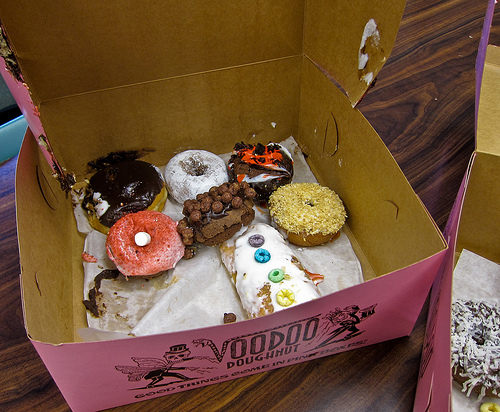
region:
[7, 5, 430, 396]
a box of donuts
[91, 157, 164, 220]
a chocolate glazed donut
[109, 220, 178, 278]
a pink donut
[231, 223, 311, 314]
a white donut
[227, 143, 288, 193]
a donut with orange frosting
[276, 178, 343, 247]
a donut with tan sprinkles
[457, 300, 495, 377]
a donut with coconut on it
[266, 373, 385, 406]
the wood table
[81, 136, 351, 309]
seven donuts in a box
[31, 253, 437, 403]
the side of the pink box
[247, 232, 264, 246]
purple Froot Loop on donut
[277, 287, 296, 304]
yellow Froot Loop on the donut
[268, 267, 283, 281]
green Froot Loop on the donut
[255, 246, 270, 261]
blue Froot Loop on a donut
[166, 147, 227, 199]
round powdered sugar donut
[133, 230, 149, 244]
small white marshmallow on pink donut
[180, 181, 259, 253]
donut with Cocoa Puffs on it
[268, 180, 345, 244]
round donut with coconut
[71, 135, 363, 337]
white paper under the donuts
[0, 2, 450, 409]
pink Voodoo Donut cardboard box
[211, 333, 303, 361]
a pink box written on voodoo doughnut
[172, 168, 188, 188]
ice on a doughnut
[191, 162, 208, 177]
a hole on a doughnut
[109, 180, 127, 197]
jam on a doughnut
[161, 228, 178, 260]
pink ice on a doughnut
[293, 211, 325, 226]
yellow ice on a doughnut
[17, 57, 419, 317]
a box full of doughnuts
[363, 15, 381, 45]
remains of a ice on the doughnut box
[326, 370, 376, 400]
a wooden table with doughnut boxes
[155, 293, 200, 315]
a white napkin in the doughnut box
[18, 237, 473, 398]
doughnut box is pink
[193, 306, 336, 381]
Voodoo doughnut is the name of the company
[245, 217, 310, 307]
long white donut with color circles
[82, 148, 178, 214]
chocolate frosting donut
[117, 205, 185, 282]
doughnut is red with marshmellow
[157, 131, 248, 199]
white powedered doughnut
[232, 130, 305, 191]
chocolate doughnut with red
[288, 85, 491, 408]
two boxes of donuts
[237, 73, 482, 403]
boxes on the table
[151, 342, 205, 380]
skull people on the box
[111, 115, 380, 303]
snacks are in a box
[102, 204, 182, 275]
the doughnut is red in colour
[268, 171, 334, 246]
the cake is yellow in colour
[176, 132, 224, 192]
the doughnut is white in colour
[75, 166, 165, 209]
the doughnut is brown in colour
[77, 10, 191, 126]
the bo x is brown on the inside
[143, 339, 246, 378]
the box is pink on the outside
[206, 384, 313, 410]
the table is brown in colour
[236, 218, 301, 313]
the cake has some toppings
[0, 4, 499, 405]
two boxes are on the table